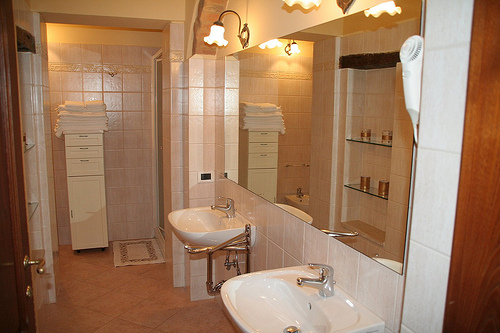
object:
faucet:
[296, 263, 336, 297]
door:
[154, 47, 172, 260]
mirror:
[219, 0, 430, 276]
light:
[202, 21, 228, 48]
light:
[275, 0, 330, 12]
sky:
[343, 127, 395, 199]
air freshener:
[399, 34, 423, 146]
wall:
[180, 1, 472, 331]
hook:
[105, 69, 120, 80]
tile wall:
[45, 43, 161, 243]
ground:
[363, 63, 413, 93]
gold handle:
[22, 255, 46, 274]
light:
[200, 9, 249, 48]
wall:
[236, 12, 285, 52]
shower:
[150, 45, 167, 243]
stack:
[54, 100, 109, 139]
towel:
[64, 100, 106, 111]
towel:
[56, 103, 106, 113]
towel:
[57, 110, 106, 118]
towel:
[61, 114, 108, 119]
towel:
[58, 119, 108, 123]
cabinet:
[54, 100, 110, 253]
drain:
[284, 326, 302, 331]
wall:
[42, 43, 221, 278]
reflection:
[339, 65, 394, 246]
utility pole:
[163, 192, 262, 254]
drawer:
[64, 133, 103, 146]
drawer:
[65, 144, 103, 158]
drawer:
[65, 158, 104, 177]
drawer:
[69, 179, 106, 251]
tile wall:
[116, 71, 146, 231]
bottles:
[358, 127, 391, 199]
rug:
[112, 238, 167, 268]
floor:
[58, 243, 259, 328]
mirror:
[225, 0, 424, 274]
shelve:
[345, 136, 391, 148]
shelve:
[345, 183, 388, 199]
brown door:
[0, 2, 55, 332]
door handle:
[16, 238, 51, 280]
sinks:
[166, 205, 384, 333]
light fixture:
[202, 7, 252, 54]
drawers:
[64, 133, 105, 177]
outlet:
[197, 170, 214, 184]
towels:
[53, 100, 107, 137]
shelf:
[345, 133, 391, 148]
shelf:
[360, 174, 390, 195]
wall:
[338, 20, 411, 275]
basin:
[168, 204, 256, 252]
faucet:
[211, 196, 237, 218]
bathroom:
[0, 1, 498, 333]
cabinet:
[59, 126, 109, 253]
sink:
[217, 263, 381, 333]